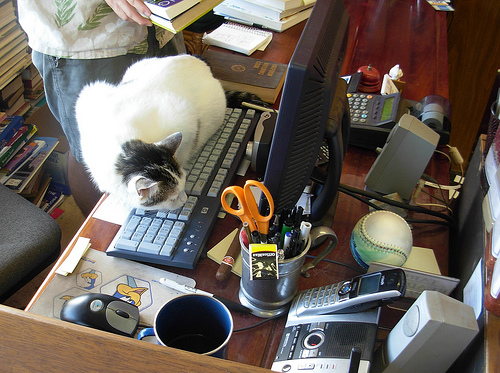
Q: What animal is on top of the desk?
A: Cat.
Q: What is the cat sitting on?
A: Computer keyboard.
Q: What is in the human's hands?
A: Books.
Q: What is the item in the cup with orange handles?
A: Scissors.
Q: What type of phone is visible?
A: Landline.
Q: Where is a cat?
A: On the desk.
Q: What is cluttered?
A: The desk.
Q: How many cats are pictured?
A: One.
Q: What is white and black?
A: The cat.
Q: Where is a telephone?
A: On desk.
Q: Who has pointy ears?
A: A cat.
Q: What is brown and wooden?
A: The desk.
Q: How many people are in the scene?
A: One.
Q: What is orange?
A: Scissors.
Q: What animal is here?
A: Cat.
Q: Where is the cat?
A: Keyboard.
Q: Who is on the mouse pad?
A: The Road Runner.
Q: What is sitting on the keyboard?
A: A cat.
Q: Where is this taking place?
A: An office.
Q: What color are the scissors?
A: Orange.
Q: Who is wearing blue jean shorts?
A: A person.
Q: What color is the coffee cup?
A: Blue.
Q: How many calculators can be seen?
A: One.